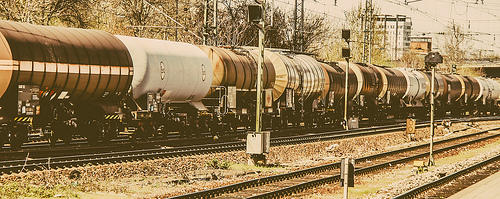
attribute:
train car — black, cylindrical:
[377, 60, 409, 113]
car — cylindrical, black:
[86, 39, 318, 137]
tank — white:
[111, 31, 215, 113]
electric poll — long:
[335, 27, 355, 140]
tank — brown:
[0, 18, 133, 100]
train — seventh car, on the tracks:
[372, 62, 399, 119]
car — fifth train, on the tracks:
[325, 56, 359, 108]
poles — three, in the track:
[252, 17, 447, 165]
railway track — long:
[0, 111, 496, 172]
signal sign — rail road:
[239, 0, 278, 169]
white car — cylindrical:
[115, 34, 213, 111]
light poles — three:
[422, 52, 442, 167]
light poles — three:
[342, 29, 350, 130]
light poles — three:
[247, 5, 271, 163]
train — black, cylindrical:
[118, 10, 493, 185]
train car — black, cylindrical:
[342, 60, 383, 122]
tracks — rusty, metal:
[4, 113, 494, 193]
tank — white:
[128, 50, 225, 122]